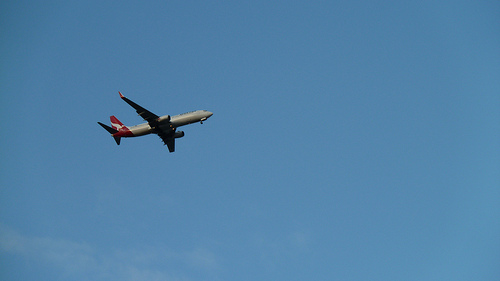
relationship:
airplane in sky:
[96, 89, 216, 159] [2, 2, 498, 277]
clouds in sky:
[42, 240, 226, 270] [18, 8, 480, 259]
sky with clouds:
[22, 13, 482, 278] [16, 230, 291, 278]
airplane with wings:
[96, 90, 214, 153] [115, 87, 178, 154]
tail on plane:
[108, 113, 128, 134] [94, 86, 212, 152]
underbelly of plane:
[118, 100, 202, 147] [99, 93, 220, 156]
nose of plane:
[191, 106, 211, 125] [94, 86, 212, 152]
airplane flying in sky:
[96, 90, 214, 153] [18, 8, 480, 259]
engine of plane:
[156, 113, 167, 125] [102, 91, 217, 149]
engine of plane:
[174, 130, 187, 140] [99, 93, 220, 156]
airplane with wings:
[96, 90, 214, 153] [121, 91, 176, 156]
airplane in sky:
[96, 90, 214, 153] [18, 8, 480, 259]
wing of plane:
[119, 93, 159, 124] [104, 93, 228, 154]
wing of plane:
[158, 130, 183, 156] [101, 94, 211, 154]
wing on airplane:
[119, 93, 160, 126] [96, 90, 214, 153]